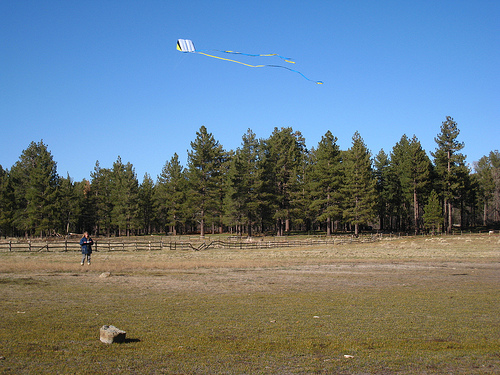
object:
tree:
[153, 152, 195, 241]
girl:
[80, 231, 94, 266]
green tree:
[6, 137, 58, 237]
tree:
[79, 157, 110, 242]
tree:
[9, 138, 54, 236]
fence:
[6, 238, 364, 251]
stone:
[99, 324, 128, 344]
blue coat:
[80, 237, 94, 255]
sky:
[1, 1, 496, 184]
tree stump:
[99, 324, 125, 344]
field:
[0, 232, 499, 373]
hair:
[83, 232, 89, 238]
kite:
[175, 38, 321, 85]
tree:
[104, 155, 138, 238]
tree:
[431, 115, 472, 233]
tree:
[332, 130, 381, 238]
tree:
[259, 119, 311, 236]